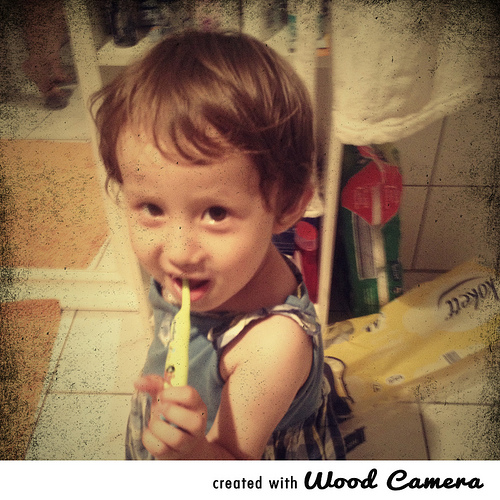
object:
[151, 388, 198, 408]
finger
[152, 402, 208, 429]
finger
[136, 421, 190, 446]
finger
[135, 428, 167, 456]
finger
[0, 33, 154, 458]
dry tree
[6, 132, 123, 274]
rug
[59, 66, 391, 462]
girl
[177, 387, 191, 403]
part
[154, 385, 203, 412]
finger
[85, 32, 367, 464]
girl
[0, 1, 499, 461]
bathroom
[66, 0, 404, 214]
plastic shelf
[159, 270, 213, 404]
toothbrush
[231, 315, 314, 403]
shoulder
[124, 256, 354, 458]
dress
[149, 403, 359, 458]
dress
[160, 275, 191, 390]
brush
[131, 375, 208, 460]
hand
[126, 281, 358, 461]
cloth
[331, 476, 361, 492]
graphic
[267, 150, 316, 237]
ear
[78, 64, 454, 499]
child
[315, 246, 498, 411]
bag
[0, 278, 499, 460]
floor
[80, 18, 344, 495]
child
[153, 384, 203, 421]
finger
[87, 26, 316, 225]
hair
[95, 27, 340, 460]
kid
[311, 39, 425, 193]
towel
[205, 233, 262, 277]
cheek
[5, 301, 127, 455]
floor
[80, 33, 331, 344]
child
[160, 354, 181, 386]
character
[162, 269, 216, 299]
mouth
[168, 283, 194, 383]
toothbrush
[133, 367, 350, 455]
pattern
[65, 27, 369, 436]
girl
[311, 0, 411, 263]
rack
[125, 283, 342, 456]
dress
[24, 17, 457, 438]
bathroom